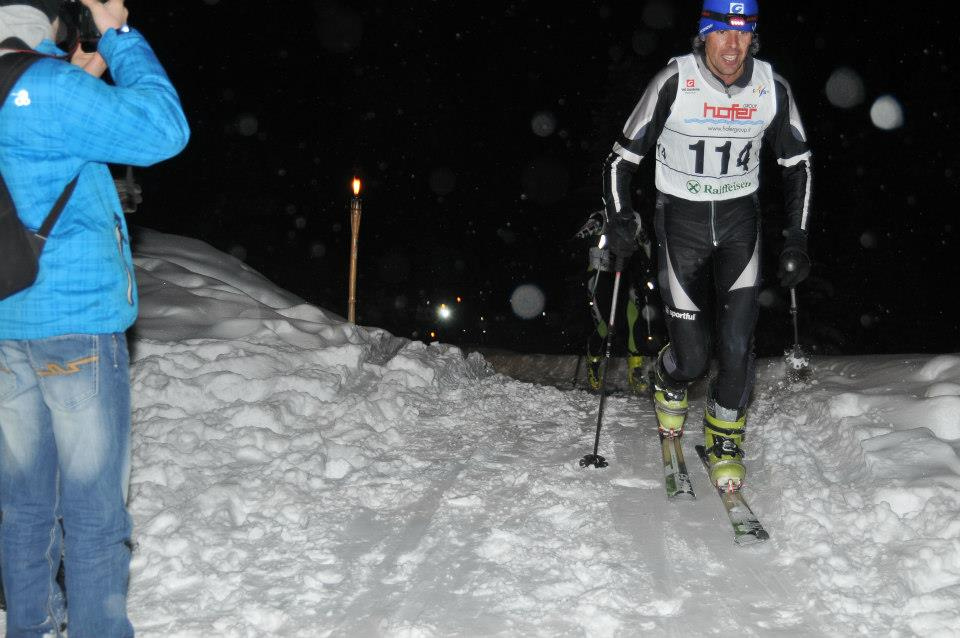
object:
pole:
[577, 238, 638, 469]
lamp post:
[349, 176, 362, 323]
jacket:
[0, 27, 193, 341]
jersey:
[654, 52, 780, 202]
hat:
[699, 0, 760, 37]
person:
[576, 210, 651, 394]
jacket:
[603, 52, 816, 229]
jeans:
[0, 331, 131, 637]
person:
[0, 0, 191, 638]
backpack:
[0, 50, 80, 304]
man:
[575, 1, 814, 547]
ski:
[694, 444, 769, 545]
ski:
[660, 436, 697, 501]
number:
[690, 140, 754, 175]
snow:
[0, 231, 960, 638]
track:
[318, 389, 826, 638]